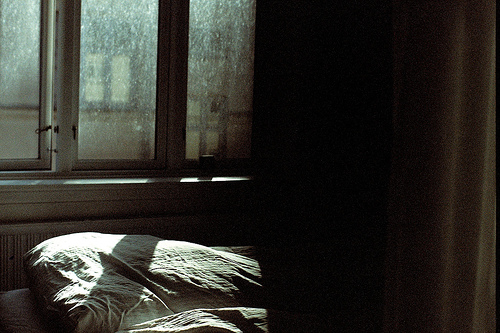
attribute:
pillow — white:
[71, 228, 275, 325]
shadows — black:
[83, 227, 157, 305]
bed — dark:
[9, 283, 65, 333]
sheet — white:
[187, 231, 269, 263]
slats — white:
[0, 234, 32, 289]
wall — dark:
[268, 13, 380, 327]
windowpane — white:
[156, 8, 188, 156]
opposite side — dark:
[260, 17, 301, 148]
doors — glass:
[6, 8, 241, 164]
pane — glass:
[0, 5, 73, 181]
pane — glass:
[89, 6, 161, 156]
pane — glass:
[193, 5, 251, 172]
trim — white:
[38, 9, 92, 171]